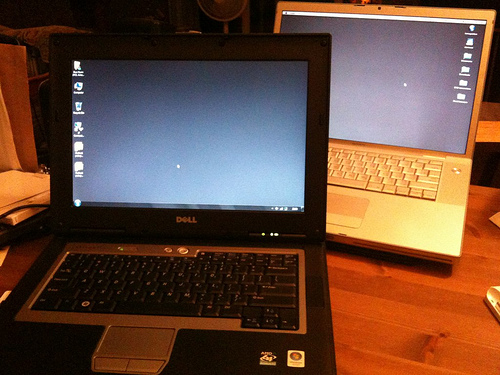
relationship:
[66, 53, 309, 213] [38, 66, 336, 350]
screen of laptop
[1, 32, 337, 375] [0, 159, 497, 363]
black computer on desk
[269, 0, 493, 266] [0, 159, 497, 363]
computer on desk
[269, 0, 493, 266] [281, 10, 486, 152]
computer with screen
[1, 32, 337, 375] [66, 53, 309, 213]
black computer with screen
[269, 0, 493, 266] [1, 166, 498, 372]
computer on table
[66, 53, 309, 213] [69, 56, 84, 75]
screen with icon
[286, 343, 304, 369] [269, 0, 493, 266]
sticker on computer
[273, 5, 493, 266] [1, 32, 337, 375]
computer behind black computer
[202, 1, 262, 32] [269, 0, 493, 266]
fan behind computer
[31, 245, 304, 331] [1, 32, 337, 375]
keyboard on a black computer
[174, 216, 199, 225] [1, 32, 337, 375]
logo on a black computer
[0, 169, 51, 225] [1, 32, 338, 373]
stack behind black computer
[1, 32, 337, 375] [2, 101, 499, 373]
black computer on front of desk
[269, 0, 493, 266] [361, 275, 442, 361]
computer on back of desk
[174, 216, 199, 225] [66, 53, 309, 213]
logo on screen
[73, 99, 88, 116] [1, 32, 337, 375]
recycle bin on black computer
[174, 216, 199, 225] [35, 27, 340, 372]
logo on laptop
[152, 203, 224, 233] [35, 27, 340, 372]
logo on laptop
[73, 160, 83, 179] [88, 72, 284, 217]
logo on screen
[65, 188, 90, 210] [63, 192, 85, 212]
start button on screen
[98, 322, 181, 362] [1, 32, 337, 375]
touchscreen on black computer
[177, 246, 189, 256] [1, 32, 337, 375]
button on black computer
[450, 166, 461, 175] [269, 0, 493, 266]
button on computer